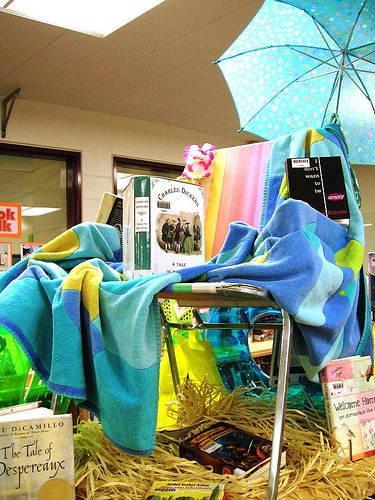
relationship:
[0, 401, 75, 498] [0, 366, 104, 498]
book of book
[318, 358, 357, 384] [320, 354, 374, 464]
pink square on book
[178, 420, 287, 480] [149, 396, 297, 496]
book in pile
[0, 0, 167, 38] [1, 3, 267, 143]
light on ceiling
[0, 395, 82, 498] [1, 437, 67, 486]
book has title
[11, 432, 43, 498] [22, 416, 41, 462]
title of a book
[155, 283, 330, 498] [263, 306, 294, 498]
beach chair has leg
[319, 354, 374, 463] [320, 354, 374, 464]
book has book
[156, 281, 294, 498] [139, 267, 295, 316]
beach chair covered with fabric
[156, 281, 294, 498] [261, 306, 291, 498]
beach chair has leg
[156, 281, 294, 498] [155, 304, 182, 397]
beach chair has leg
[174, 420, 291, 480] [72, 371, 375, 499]
book laying on top of hay